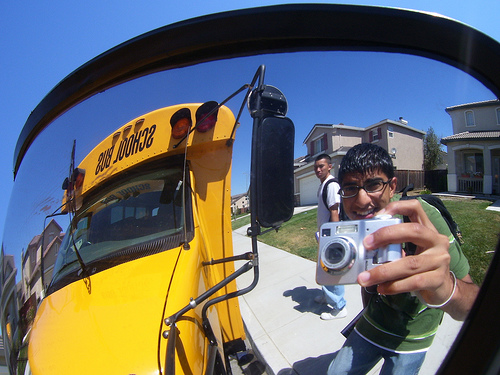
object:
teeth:
[356, 210, 373, 215]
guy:
[313, 154, 347, 321]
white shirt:
[315, 174, 341, 223]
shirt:
[350, 197, 472, 355]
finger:
[375, 271, 437, 295]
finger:
[357, 252, 438, 290]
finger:
[363, 223, 439, 251]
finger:
[377, 198, 435, 237]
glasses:
[337, 177, 395, 200]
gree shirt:
[354, 201, 471, 354]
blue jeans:
[323, 328, 426, 374]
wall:
[383, 132, 423, 173]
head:
[338, 143, 399, 219]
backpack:
[400, 186, 464, 256]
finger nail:
[356, 270, 370, 288]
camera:
[315, 218, 403, 285]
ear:
[389, 177, 397, 198]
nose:
[354, 188, 372, 207]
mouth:
[352, 208, 375, 218]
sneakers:
[281, 285, 342, 316]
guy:
[325, 141, 481, 373]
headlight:
[170, 108, 189, 139]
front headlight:
[67, 165, 85, 185]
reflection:
[100, 170, 185, 225]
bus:
[1, 63, 296, 374]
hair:
[337, 142, 391, 177]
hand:
[357, 198, 452, 297]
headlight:
[192, 101, 221, 131]